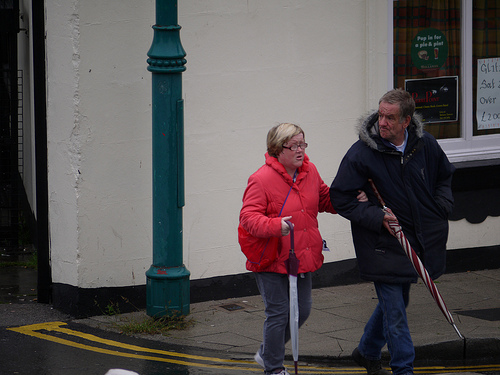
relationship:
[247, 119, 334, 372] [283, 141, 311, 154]
woman has glasses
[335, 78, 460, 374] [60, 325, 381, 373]
man crosses street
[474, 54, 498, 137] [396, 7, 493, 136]
sign in window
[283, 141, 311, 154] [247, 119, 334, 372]
glasses on woman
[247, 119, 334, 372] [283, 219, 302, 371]
woman hold umbrella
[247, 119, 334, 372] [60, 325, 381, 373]
woman cross street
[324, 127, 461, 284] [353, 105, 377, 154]
coat has hood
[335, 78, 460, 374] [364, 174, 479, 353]
man holds umbrella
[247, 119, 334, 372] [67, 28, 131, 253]
woman in front of wall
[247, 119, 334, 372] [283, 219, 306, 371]
woman holds umbrella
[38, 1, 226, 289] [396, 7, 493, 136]
building has window